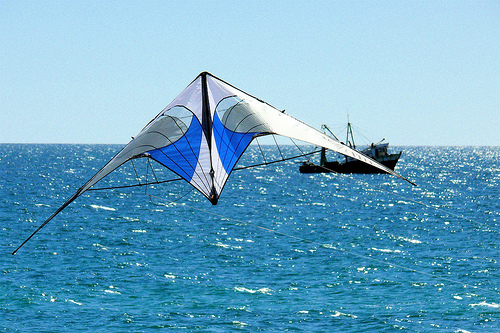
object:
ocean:
[0, 144, 498, 332]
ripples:
[202, 237, 240, 253]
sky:
[2, 2, 494, 143]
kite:
[10, 72, 420, 266]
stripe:
[85, 103, 213, 208]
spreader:
[14, 72, 423, 254]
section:
[209, 91, 252, 116]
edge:
[205, 72, 419, 187]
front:
[380, 152, 401, 172]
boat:
[299, 108, 404, 174]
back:
[297, 161, 307, 177]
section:
[4, 5, 62, 32]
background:
[0, 0, 496, 145]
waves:
[215, 277, 279, 300]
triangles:
[192, 73, 424, 208]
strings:
[134, 190, 498, 297]